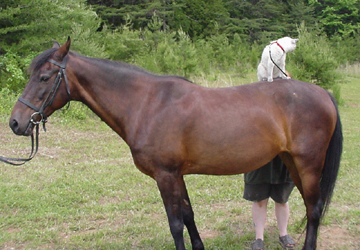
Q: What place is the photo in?
A: It is at the field.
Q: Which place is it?
A: It is a field.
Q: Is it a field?
A: Yes, it is a field.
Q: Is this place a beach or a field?
A: It is a field.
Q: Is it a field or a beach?
A: It is a field.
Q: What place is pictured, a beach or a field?
A: It is a field.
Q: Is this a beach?
A: No, it is a field.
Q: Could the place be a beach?
A: No, it is a field.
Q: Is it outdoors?
A: Yes, it is outdoors.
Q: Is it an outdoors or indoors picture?
A: It is outdoors.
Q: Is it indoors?
A: No, it is outdoors.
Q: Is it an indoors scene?
A: No, it is outdoors.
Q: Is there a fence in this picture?
A: No, there are no fences.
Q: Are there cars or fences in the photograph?
A: No, there are no fences or cars.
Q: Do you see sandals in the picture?
A: Yes, there are sandals.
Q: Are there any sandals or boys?
A: Yes, there are sandals.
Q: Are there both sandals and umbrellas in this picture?
A: No, there are sandals but no umbrellas.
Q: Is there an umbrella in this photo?
A: No, there are no umbrellas.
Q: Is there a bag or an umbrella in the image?
A: No, there are no umbrellas or bags.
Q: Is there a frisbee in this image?
A: No, there are no frisbees.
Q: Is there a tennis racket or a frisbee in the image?
A: No, there are no frisbees or rackets.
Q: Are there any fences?
A: No, there are no fences.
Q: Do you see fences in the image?
A: No, there are no fences.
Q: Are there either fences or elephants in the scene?
A: No, there are no fences or elephants.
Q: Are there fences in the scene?
A: No, there are no fences.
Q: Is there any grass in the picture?
A: Yes, there is grass.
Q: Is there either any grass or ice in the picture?
A: Yes, there is grass.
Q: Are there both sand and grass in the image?
A: No, there is grass but no sand.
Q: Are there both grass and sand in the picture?
A: No, there is grass but no sand.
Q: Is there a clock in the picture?
A: No, there are no clocks.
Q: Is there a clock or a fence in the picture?
A: No, there are no clocks or fences.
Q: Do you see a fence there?
A: No, there are no fences.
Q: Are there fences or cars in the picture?
A: No, there are no fences or cars.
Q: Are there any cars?
A: No, there are no cars.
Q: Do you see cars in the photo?
A: No, there are no cars.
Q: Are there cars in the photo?
A: No, there are no cars.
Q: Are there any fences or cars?
A: No, there are no cars or fences.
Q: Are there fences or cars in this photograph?
A: No, there are no cars or fences.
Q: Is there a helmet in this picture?
A: No, there are no helmets.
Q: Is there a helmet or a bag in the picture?
A: No, there are no helmets or bags.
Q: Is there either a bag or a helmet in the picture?
A: No, there are no helmets or bags.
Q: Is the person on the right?
A: Yes, the person is on the right of the image.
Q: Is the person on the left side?
A: No, the person is on the right of the image.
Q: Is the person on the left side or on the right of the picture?
A: The person is on the right of the image.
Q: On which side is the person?
A: The person is on the right of the image.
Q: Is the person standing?
A: Yes, the person is standing.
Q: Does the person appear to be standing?
A: Yes, the person is standing.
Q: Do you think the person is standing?
A: Yes, the person is standing.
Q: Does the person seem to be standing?
A: Yes, the person is standing.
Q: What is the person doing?
A: The person is standing.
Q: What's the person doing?
A: The person is standing.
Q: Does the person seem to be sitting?
A: No, the person is standing.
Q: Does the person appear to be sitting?
A: No, the person is standing.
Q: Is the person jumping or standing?
A: The person is standing.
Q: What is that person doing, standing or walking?
A: The person is standing.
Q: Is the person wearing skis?
A: No, the person is wearing sandals.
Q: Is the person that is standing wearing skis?
A: No, the person is wearing sandals.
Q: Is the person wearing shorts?
A: Yes, the person is wearing shorts.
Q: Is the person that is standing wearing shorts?
A: Yes, the person is wearing shorts.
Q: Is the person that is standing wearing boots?
A: No, the person is wearing shorts.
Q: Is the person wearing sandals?
A: Yes, the person is wearing sandals.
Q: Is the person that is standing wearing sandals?
A: Yes, the person is wearing sandals.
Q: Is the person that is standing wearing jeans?
A: No, the person is wearing sandals.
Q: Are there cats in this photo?
A: Yes, there is a cat.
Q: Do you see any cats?
A: Yes, there is a cat.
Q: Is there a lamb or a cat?
A: Yes, there is a cat.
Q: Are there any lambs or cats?
A: Yes, there is a cat.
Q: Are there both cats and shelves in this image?
A: No, there is a cat but no shelves.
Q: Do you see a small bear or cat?
A: Yes, there is a small cat.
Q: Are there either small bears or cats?
A: Yes, there is a small cat.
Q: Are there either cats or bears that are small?
A: Yes, the cat is small.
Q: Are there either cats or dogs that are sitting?
A: Yes, the cat is sitting.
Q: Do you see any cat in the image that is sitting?
A: Yes, there is a cat that is sitting.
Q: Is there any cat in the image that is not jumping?
A: Yes, there is a cat that is sitting.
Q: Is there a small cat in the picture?
A: Yes, there is a small cat.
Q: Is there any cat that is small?
A: Yes, there is a cat that is small.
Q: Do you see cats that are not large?
A: Yes, there is a small cat.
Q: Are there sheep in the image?
A: No, there are no sheep.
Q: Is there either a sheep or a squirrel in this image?
A: No, there are no sheep or squirrels.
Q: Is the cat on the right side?
A: Yes, the cat is on the right of the image.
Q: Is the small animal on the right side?
A: Yes, the cat is on the right of the image.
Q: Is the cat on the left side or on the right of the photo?
A: The cat is on the right of the image.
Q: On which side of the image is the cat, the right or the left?
A: The cat is on the right of the image.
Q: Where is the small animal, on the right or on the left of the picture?
A: The cat is on the right of the image.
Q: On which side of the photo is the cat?
A: The cat is on the right of the image.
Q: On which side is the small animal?
A: The cat is on the right of the image.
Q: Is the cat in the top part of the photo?
A: Yes, the cat is in the top of the image.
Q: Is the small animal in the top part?
A: Yes, the cat is in the top of the image.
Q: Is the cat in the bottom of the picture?
A: No, the cat is in the top of the image.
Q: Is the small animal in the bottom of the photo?
A: No, the cat is in the top of the image.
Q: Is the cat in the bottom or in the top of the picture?
A: The cat is in the top of the image.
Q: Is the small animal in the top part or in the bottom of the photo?
A: The cat is in the top of the image.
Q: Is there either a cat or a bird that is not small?
A: No, there is a cat but it is small.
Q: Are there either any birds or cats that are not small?
A: No, there is a cat but it is small.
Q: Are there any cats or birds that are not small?
A: No, there is a cat but it is small.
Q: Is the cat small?
A: Yes, the cat is small.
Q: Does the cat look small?
A: Yes, the cat is small.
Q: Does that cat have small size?
A: Yes, the cat is small.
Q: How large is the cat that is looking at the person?
A: The cat is small.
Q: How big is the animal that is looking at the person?
A: The cat is small.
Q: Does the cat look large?
A: No, the cat is small.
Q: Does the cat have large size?
A: No, the cat is small.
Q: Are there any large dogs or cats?
A: No, there is a cat but it is small.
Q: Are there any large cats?
A: No, there is a cat but it is small.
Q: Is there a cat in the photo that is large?
A: No, there is a cat but it is small.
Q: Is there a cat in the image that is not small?
A: No, there is a cat but it is small.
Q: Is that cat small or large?
A: The cat is small.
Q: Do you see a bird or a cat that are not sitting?
A: No, there is a cat but it is sitting.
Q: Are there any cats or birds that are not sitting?
A: No, there is a cat but it is sitting.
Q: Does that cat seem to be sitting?
A: Yes, the cat is sitting.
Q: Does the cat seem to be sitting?
A: Yes, the cat is sitting.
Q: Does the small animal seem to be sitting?
A: Yes, the cat is sitting.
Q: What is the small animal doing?
A: The cat is sitting.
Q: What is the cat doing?
A: The cat is sitting.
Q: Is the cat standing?
A: No, the cat is sitting.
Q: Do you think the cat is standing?
A: No, the cat is sitting.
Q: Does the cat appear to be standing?
A: No, the cat is sitting.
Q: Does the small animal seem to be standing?
A: No, the cat is sitting.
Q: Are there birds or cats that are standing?
A: No, there is a cat but it is sitting.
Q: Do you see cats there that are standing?
A: No, there is a cat but it is sitting.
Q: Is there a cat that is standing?
A: No, there is a cat but it is sitting.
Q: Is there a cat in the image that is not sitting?
A: No, there is a cat but it is sitting.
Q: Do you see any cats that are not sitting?
A: No, there is a cat but it is sitting.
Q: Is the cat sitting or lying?
A: The cat is sitting.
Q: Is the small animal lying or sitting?
A: The cat is sitting.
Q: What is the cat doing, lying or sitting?
A: The cat is sitting.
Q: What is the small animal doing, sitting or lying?
A: The cat is sitting.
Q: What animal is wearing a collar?
A: The cat is wearing a collar.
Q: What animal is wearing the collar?
A: The cat is wearing a collar.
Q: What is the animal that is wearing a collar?
A: The animal is a cat.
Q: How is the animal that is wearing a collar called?
A: The animal is a cat.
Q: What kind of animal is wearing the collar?
A: The animal is a cat.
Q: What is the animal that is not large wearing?
A: The cat is wearing a collar.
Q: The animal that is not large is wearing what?
A: The cat is wearing a collar.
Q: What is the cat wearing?
A: The cat is wearing a collar.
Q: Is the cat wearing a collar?
A: Yes, the cat is wearing a collar.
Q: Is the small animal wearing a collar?
A: Yes, the cat is wearing a collar.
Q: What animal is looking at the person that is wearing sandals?
A: The cat is looking at the person.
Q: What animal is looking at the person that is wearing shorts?
A: The cat is looking at the person.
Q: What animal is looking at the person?
A: The cat is looking at the person.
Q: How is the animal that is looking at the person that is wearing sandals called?
A: The animal is a cat.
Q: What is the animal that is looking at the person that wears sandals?
A: The animal is a cat.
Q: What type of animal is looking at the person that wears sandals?
A: The animal is a cat.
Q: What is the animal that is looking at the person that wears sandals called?
A: The animal is a cat.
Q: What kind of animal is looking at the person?
A: The animal is a cat.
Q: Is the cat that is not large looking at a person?
A: Yes, the cat is looking at a person.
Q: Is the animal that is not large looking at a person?
A: Yes, the cat is looking at a person.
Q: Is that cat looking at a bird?
A: No, the cat is looking at a person.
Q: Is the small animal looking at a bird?
A: No, the cat is looking at a person.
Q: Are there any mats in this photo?
A: No, there are no mats.